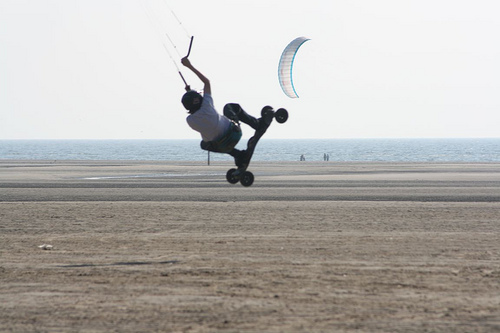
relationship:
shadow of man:
[65, 239, 155, 287] [180, 55, 270, 168]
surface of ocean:
[73, 126, 117, 145] [0, 138, 499, 161]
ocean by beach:
[289, 114, 493, 176] [227, 175, 498, 295]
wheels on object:
[200, 170, 300, 198] [277, 38, 338, 60]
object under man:
[234, 106, 355, 215] [180, 55, 270, 168]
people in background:
[286, 143, 381, 188] [289, 114, 493, 176]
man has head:
[146, 65, 226, 145] [177, 77, 214, 117]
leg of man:
[220, 110, 261, 150] [146, 65, 226, 145]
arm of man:
[187, 69, 217, 90] [146, 65, 226, 145]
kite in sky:
[250, 39, 302, 87] [362, 19, 498, 77]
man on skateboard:
[180, 55, 270, 168] [231, 102, 276, 174]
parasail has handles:
[147, 9, 330, 83] [164, 24, 203, 95]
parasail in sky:
[147, 9, 330, 83] [362, 19, 498, 77]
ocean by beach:
[0, 138, 499, 161] [227, 175, 498, 295]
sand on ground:
[346, 213, 475, 267] [53, 191, 374, 285]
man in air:
[146, 65, 226, 145] [115, 10, 400, 165]